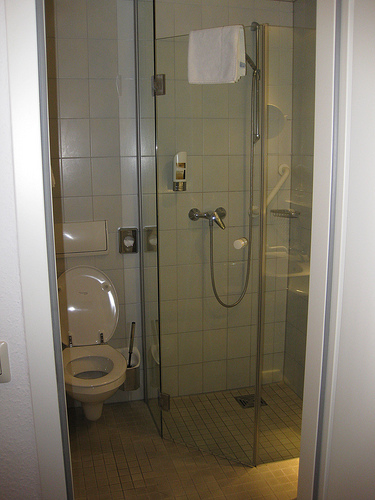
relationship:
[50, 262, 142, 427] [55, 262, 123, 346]
toilet has lid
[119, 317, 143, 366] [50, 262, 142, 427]
brush next to toilet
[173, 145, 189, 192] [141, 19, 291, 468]
shampoo near door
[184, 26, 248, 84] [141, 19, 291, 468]
towel over door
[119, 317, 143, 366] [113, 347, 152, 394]
brush in holder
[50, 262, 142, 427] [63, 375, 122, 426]
toilet has bowl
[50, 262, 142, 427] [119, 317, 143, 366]
toilet near brush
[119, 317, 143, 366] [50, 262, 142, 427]
brush near toilet